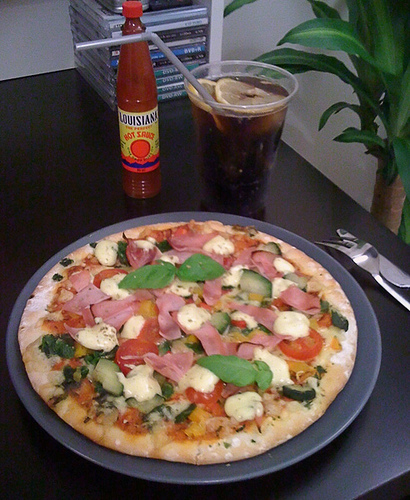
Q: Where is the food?
A: Table.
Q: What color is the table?
A: Black.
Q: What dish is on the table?
A: Pizza.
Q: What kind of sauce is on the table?
A: Hot.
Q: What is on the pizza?
A: Cheese.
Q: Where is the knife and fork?
A: Beside plate.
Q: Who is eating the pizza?
A: No one.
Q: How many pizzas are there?
A: One.